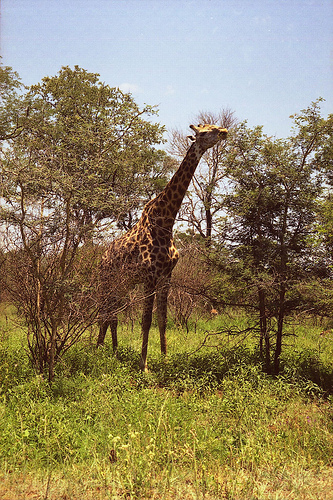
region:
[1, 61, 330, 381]
Giraffe standing among group of trees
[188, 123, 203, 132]
Horns on top of giraffe's head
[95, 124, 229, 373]
Giraffe eating leaves on tree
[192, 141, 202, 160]
White area on giraffe's neck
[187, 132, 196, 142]
Ear on side of giraffe's head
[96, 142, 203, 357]
Spots on giraffe's body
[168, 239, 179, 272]
Bump on side of giraffe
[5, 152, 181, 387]
Dead tree in front of giraffe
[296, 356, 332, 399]
Shadow of tree on ground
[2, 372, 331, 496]
Green plants in front of giraffe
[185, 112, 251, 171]
face of the giraffe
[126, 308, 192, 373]
front legs of the giraffe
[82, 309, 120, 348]
back legs of the giraffe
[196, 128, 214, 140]
eye of the giraffe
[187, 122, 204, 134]
ear of the giraffe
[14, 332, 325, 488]
a beautiful view of grass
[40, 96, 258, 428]
a long giraffe in field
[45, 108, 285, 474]
a giraffe in forest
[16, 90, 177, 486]
a beautiful view of tree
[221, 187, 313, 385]
a group of trees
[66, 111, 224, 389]
tall giraffe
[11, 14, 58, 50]
white clouds in blue sky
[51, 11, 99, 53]
white clouds in blue sky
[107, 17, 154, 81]
white clouds in blue sky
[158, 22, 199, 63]
white clouds in blue sky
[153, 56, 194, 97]
white clouds in blue sky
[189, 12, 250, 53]
white clouds in blue sky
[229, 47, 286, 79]
white clouds in blue sky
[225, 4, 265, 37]
white clouds in blue sky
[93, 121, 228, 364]
The giraffe is spotted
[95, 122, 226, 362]
The giraffe is brown and yellow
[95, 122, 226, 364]
The spots are brown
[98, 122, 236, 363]
The giraffe is eating the leaves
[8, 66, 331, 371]
The giraffe is near the trees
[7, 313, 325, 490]
Tall green and brown grass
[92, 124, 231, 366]
The giraffe is standing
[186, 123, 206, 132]
The giraffe has horns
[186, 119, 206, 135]
The horns have black tips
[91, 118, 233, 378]
Giraffe standing on grass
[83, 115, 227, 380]
tall brown giraffe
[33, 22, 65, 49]
white clouds in blue sky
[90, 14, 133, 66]
white clouds in blue sky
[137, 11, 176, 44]
white clouds in blue sky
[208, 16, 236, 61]
white clouds in blue sky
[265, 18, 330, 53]
white clouds in blue sky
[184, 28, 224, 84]
white clouds in blue sky